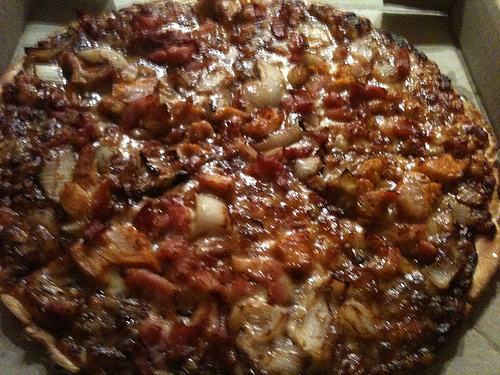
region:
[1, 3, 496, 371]
blurry pizza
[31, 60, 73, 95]
onion on the pizza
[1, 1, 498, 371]
fattening pizza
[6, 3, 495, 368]
a fully cooked pizza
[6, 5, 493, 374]
a pizza with melted toppings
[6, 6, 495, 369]
a hot cooked pizza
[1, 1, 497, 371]
A large round pizza that looks slimy.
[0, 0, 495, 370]
A large mostly burnt pizza.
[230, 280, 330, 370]
Clump of onions down on the bottom piece.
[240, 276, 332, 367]
A section of white onions at the bottom.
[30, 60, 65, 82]
A visible white onion on the top left.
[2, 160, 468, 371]
Largest triangle of pizza with large section of onion.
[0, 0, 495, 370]
A large burnt pizza with onion and ham.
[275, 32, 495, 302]
A right triangle piece of pizza.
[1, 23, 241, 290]
A left triangle of pizza with onions.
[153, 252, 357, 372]
Part of a pizza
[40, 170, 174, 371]
Part of a pizza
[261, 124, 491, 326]
Part of a pizza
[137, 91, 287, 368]
Part of a pizza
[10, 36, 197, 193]
Part of a pizza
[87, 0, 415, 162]
Part of a pizza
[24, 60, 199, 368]
Part of a pizza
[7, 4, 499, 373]
A large shiny pizza.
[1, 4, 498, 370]
A large dark crust pizza with onions.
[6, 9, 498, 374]
A large ham and onion pizza.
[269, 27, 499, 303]
Large right slice of pizza with onion and ham.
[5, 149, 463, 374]
Bottom most slice of onion pizza.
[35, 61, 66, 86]
Most visible in focus onion to the upper left.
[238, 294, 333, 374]
Bottom little area of onions.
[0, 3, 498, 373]
A brown crust pizza with onions.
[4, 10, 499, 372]
A large semi-burnt pizza with onions.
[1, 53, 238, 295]
Left piece of onion and ham pizza.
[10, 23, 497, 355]
a pizza on a table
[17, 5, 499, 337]
a pizza that is cooked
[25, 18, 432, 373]
a pizza that is baked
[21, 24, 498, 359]
a pizza that is sliced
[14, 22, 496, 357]
a pizza that is cut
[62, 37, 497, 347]
a pizza with cheese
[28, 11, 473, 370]
cheese melted on a pizza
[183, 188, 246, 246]
onions on a pizza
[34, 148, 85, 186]
onion on a pizza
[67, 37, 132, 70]
onion on a pizza